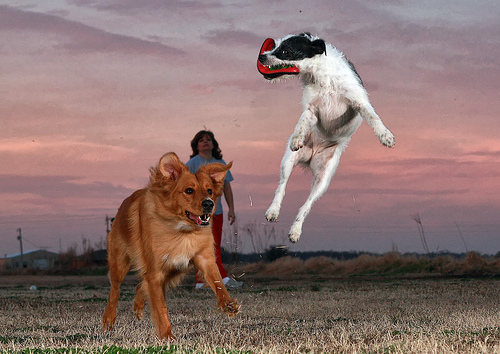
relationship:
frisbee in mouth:
[253, 33, 302, 79] [263, 56, 299, 77]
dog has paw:
[262, 28, 397, 248] [288, 135, 307, 154]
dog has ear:
[262, 28, 397, 248] [313, 37, 330, 62]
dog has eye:
[262, 28, 397, 248] [279, 45, 292, 57]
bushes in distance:
[220, 243, 380, 260] [25, 233, 464, 283]